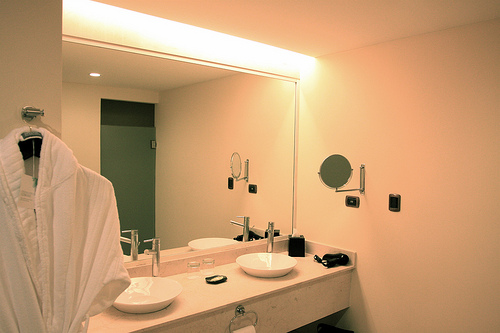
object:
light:
[90, 73, 101, 77]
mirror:
[61, 37, 297, 260]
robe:
[1, 127, 130, 332]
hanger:
[20, 126, 44, 142]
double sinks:
[236, 252, 296, 277]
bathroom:
[1, 1, 499, 333]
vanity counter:
[178, 255, 262, 299]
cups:
[187, 262, 201, 280]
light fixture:
[64, 0, 319, 81]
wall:
[64, 1, 499, 332]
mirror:
[319, 153, 354, 190]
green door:
[99, 97, 158, 250]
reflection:
[89, 72, 100, 77]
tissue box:
[287, 235, 306, 257]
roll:
[232, 323, 261, 333]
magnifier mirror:
[230, 152, 250, 184]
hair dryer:
[314, 253, 350, 268]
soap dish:
[205, 274, 228, 284]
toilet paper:
[232, 326, 258, 333]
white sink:
[186, 237, 235, 252]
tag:
[18, 175, 35, 210]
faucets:
[265, 221, 275, 254]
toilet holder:
[227, 305, 255, 333]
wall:
[1, 1, 58, 106]